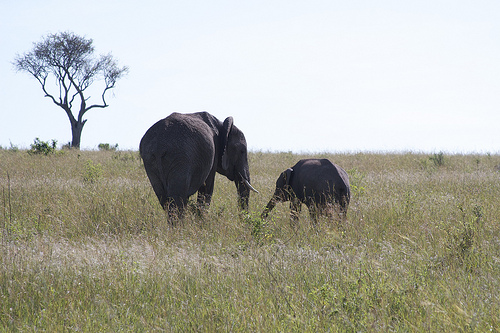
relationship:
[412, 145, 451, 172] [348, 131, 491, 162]
bush on horizon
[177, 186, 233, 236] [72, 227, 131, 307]
leg by grass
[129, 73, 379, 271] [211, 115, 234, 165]
elephant has ear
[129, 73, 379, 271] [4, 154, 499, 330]
elephant in field